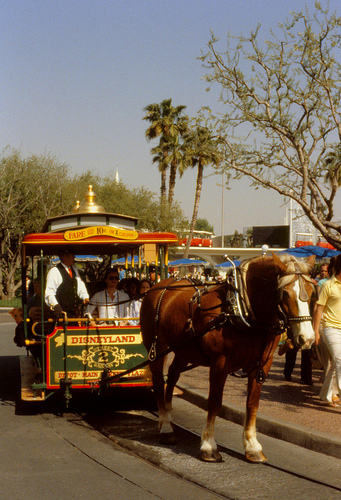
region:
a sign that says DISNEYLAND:
[56, 330, 142, 351]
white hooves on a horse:
[152, 406, 266, 472]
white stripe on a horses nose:
[292, 277, 312, 344]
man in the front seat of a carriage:
[90, 270, 131, 323]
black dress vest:
[50, 263, 87, 318]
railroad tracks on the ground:
[76, 398, 339, 498]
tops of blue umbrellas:
[59, 241, 335, 269]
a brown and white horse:
[124, 249, 331, 463]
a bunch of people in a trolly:
[17, 252, 154, 347]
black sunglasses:
[107, 272, 119, 283]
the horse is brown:
[141, 259, 281, 441]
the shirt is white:
[87, 288, 126, 323]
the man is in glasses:
[89, 267, 134, 324]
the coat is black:
[56, 268, 85, 312]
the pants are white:
[325, 328, 340, 370]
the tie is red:
[66, 265, 74, 276]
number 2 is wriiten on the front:
[92, 349, 116, 363]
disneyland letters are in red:
[72, 332, 134, 350]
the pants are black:
[282, 353, 307, 374]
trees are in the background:
[21, 170, 188, 223]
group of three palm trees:
[142, 101, 221, 274]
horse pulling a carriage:
[139, 255, 320, 463]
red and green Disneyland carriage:
[20, 184, 184, 402]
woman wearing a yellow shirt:
[312, 254, 340, 406]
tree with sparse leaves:
[198, 1, 340, 250]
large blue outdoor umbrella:
[167, 256, 208, 276]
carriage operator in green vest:
[44, 247, 89, 329]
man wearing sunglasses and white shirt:
[82, 268, 131, 324]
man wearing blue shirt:
[314, 262, 333, 288]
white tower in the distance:
[113, 165, 122, 188]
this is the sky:
[73, 125, 105, 153]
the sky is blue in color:
[100, 133, 121, 163]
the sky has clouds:
[82, 146, 127, 182]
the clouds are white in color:
[108, 137, 126, 159]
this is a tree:
[11, 169, 67, 206]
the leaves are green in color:
[24, 177, 55, 192]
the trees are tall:
[140, 94, 215, 218]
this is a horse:
[140, 250, 313, 390]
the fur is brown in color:
[162, 296, 184, 325]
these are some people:
[65, 264, 138, 322]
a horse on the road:
[101, 222, 331, 435]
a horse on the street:
[153, 259, 329, 469]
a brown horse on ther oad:
[121, 257, 337, 436]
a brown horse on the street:
[130, 253, 328, 478]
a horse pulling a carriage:
[23, 201, 286, 400]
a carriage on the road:
[61, 234, 207, 462]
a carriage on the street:
[20, 226, 153, 416]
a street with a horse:
[58, 277, 335, 479]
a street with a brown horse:
[83, 253, 340, 480]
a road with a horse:
[139, 238, 295, 408]